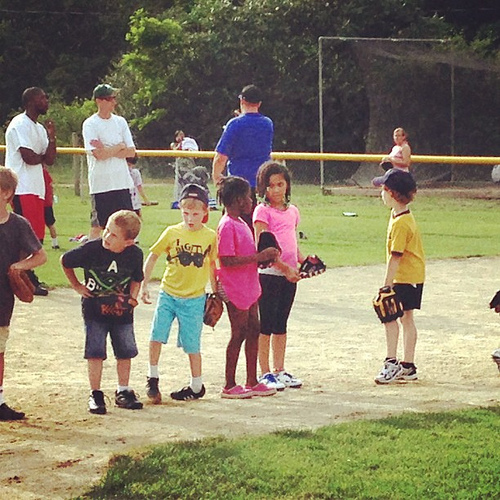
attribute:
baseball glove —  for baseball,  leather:
[373, 287, 404, 323]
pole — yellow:
[303, 144, 498, 176]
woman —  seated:
[371, 124, 413, 197]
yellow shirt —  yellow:
[162, 230, 228, 298]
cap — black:
[242, 78, 281, 108]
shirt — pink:
[214, 215, 262, 311]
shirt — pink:
[251, 203, 300, 270]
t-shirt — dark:
[62, 237, 145, 325]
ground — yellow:
[381, 176, 405, 208]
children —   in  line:
[3, 163, 424, 384]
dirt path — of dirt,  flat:
[0, 253, 499, 495]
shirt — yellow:
[154, 219, 225, 304]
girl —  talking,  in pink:
[252, 154, 335, 401]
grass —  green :
[288, 439, 419, 486]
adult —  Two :
[80, 82, 137, 229]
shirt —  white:
[77, 113, 134, 193]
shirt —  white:
[3, 113, 48, 197]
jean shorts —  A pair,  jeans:
[78, 313, 141, 363]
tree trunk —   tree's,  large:
[341, 37, 461, 182]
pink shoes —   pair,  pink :
[224, 385, 251, 400]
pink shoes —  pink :
[252, 382, 275, 397]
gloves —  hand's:
[371, 283, 405, 323]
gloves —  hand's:
[297, 252, 326, 279]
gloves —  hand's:
[202, 289, 224, 329]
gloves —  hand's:
[110, 292, 140, 317]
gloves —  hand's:
[7, 267, 48, 302]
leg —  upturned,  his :
[149, 311, 169, 396]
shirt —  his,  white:
[78, 115, 138, 194]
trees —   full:
[10, 1, 499, 183]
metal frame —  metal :
[316, 31, 478, 186]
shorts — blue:
[149, 287, 205, 352]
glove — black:
[373, 281, 406, 321]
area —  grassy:
[97, 414, 497, 497]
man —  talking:
[209, 82, 275, 192]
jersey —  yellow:
[150, 222, 217, 296]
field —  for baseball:
[0, 183, 499, 497]